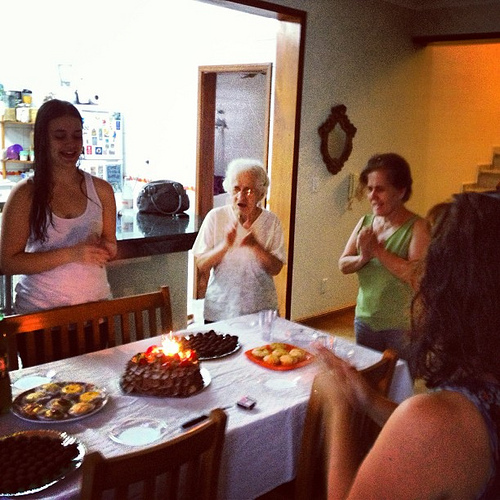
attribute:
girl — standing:
[28, 111, 94, 375]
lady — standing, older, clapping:
[220, 160, 298, 310]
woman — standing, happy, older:
[352, 154, 397, 339]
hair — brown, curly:
[454, 211, 499, 338]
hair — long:
[21, 100, 55, 230]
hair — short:
[377, 140, 413, 208]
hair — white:
[234, 159, 285, 202]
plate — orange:
[272, 364, 292, 377]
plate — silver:
[230, 340, 242, 361]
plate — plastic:
[124, 411, 173, 452]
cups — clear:
[252, 310, 284, 341]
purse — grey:
[132, 174, 197, 220]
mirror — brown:
[311, 106, 356, 159]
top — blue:
[457, 388, 499, 424]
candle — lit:
[156, 337, 187, 349]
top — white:
[63, 233, 100, 287]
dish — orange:
[246, 340, 308, 372]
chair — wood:
[106, 294, 175, 336]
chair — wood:
[30, 301, 75, 350]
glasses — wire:
[228, 190, 268, 195]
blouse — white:
[204, 206, 246, 300]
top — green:
[363, 271, 407, 322]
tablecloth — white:
[230, 423, 292, 498]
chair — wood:
[101, 453, 178, 491]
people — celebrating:
[27, 97, 452, 270]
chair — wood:
[379, 360, 396, 408]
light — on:
[431, 52, 488, 135]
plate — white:
[293, 332, 319, 344]